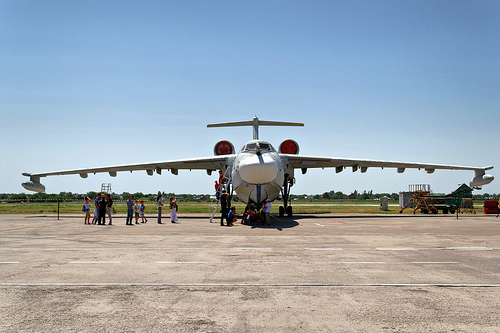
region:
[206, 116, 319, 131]
the tail wing of a plane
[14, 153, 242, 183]
the wing of a plane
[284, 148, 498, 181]
the wing of a plane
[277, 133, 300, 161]
the engine a plane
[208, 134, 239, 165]
the engine a plane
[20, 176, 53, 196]
the engine a plane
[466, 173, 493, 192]
the engine a plane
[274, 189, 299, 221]
the landing gear of a plane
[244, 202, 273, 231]
the landing gear of a plane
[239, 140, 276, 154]
the front windows of a plane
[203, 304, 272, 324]
Part of the ground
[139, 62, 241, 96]
Part of the blue sky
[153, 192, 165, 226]
A person standing in distance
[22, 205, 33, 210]
Part of the green grass in distance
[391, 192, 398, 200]
Part of the tree in distance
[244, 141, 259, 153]
A window on the airplane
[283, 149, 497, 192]
The left wing of the airplane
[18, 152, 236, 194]
The right wing of the airplane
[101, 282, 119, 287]
Part of the white line on the ground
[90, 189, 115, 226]
Three people standing together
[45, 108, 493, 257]
An airplane with people outside.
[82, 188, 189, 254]
People standing outside of an airplane.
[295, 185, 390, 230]
Trees on the horizon.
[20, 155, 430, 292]
An airplane at a airport.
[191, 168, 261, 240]
People entering an airplane.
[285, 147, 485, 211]
The wing of an airplane.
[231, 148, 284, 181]
The nose of the airplane is white.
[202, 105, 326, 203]
The tail of the plane is gray.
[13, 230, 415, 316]
White lines painted on the runway.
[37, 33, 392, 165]
The sky is clear and blue.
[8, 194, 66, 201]
trees behind the plane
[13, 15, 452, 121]
the sky above the airplane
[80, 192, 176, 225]
people standing by the airplane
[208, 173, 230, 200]
the stairs on the airplane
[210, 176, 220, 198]
a person coming down the stairs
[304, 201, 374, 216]
the grass behind the airplane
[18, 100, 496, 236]
a large white airplane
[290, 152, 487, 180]
the wing on the airplane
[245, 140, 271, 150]
the windshield on the airplane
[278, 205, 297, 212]
a wheel on the airplane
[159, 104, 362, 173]
the train has red jets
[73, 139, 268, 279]
people are waiting to board the plane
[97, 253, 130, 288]
dirt is on the ground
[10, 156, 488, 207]
the plane is wide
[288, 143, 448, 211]
the wings are long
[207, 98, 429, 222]
the propeller is on top of the plane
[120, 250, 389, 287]
whtie lines are on the ground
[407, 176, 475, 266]
the ladder is made of wood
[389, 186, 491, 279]
a cargo is green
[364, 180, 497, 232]
a scaffolding is by the plane